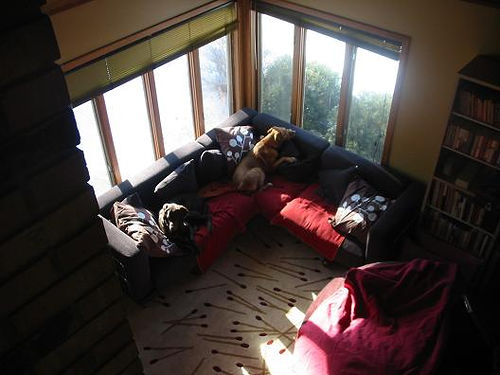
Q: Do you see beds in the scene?
A: No, there are no beds.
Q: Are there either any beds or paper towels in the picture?
A: No, there are no beds or paper towels.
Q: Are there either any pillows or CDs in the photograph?
A: Yes, there is a pillow.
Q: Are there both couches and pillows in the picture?
A: Yes, there are both a pillow and a couch.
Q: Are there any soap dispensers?
A: No, there are no soap dispensers.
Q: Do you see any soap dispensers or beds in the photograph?
A: No, there are no soap dispensers or beds.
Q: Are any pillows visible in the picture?
A: Yes, there is a pillow.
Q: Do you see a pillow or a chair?
A: Yes, there is a pillow.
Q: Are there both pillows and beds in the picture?
A: No, there is a pillow but no beds.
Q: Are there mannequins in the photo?
A: No, there are no mannequins.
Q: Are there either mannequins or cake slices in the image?
A: No, there are no mannequins or cake slices.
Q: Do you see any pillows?
A: Yes, there is a pillow.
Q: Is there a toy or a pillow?
A: Yes, there is a pillow.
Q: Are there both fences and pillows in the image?
A: No, there is a pillow but no fences.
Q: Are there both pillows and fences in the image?
A: No, there is a pillow but no fences.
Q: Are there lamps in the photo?
A: No, there are no lamps.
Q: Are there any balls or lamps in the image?
A: No, there are no lamps or balls.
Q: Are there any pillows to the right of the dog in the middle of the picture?
A: Yes, there is a pillow to the right of the dog.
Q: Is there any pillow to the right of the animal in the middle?
A: Yes, there is a pillow to the right of the dog.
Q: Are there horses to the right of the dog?
A: No, there is a pillow to the right of the dog.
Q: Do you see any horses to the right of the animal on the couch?
A: No, there is a pillow to the right of the dog.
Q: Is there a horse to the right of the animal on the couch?
A: No, there is a pillow to the right of the dog.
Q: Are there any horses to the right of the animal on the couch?
A: No, there is a pillow to the right of the dog.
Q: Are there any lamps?
A: No, there are no lamps.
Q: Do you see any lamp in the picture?
A: No, there are no lamps.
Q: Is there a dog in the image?
A: Yes, there is a dog.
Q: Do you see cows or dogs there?
A: Yes, there is a dog.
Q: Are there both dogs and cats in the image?
A: No, there is a dog but no cats.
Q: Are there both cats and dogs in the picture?
A: No, there is a dog but no cats.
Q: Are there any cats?
A: No, there are no cats.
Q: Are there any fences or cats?
A: No, there are no cats or fences.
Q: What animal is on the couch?
A: The animal is a dog.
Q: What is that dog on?
A: The dog is on the couch.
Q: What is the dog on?
A: The dog is on the couch.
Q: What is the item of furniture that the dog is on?
A: The piece of furniture is a couch.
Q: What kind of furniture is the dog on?
A: The dog is on the couch.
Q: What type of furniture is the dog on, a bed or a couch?
A: The dog is on a couch.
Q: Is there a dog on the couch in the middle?
A: Yes, there is a dog on the couch.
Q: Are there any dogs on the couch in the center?
A: Yes, there is a dog on the couch.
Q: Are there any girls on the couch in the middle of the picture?
A: No, there is a dog on the couch.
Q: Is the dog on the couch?
A: Yes, the dog is on the couch.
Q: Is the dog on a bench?
A: No, the dog is on the couch.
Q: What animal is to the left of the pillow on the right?
A: The animal is a dog.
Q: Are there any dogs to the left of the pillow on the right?
A: Yes, there is a dog to the left of the pillow.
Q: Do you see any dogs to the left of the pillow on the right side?
A: Yes, there is a dog to the left of the pillow.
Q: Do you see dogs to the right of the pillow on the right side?
A: No, the dog is to the left of the pillow.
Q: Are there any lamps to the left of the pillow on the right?
A: No, there is a dog to the left of the pillow.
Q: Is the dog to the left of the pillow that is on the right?
A: Yes, the dog is to the left of the pillow.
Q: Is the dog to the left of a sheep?
A: No, the dog is to the left of the pillow.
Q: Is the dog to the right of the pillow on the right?
A: No, the dog is to the left of the pillow.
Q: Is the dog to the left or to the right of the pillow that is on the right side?
A: The dog is to the left of the pillow.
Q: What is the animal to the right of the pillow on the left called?
A: The animal is a dog.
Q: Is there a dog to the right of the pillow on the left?
A: Yes, there is a dog to the right of the pillow.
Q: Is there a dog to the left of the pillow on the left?
A: No, the dog is to the right of the pillow.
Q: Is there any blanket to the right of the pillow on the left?
A: No, there is a dog to the right of the pillow.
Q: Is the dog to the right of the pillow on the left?
A: Yes, the dog is to the right of the pillow.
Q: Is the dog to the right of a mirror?
A: No, the dog is to the right of the pillow.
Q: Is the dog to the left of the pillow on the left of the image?
A: No, the dog is to the right of the pillow.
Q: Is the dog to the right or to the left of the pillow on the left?
A: The dog is to the right of the pillow.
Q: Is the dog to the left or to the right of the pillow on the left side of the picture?
A: The dog is to the right of the pillow.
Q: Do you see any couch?
A: Yes, there is a couch.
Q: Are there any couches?
A: Yes, there is a couch.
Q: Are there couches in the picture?
A: Yes, there is a couch.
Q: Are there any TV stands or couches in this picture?
A: Yes, there is a couch.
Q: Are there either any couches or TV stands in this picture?
A: Yes, there is a couch.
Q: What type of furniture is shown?
A: The furniture is a couch.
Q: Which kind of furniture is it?
A: The piece of furniture is a couch.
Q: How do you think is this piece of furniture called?
A: That is a couch.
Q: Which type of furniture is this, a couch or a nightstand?
A: That is a couch.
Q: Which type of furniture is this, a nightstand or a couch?
A: That is a couch.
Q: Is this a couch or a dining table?
A: This is a couch.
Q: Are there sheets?
A: No, there are no sheets.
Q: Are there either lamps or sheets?
A: No, there are no sheets or lamps.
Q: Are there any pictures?
A: No, there are no pictures.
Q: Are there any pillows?
A: Yes, there is a pillow.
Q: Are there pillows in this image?
A: Yes, there is a pillow.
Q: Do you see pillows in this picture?
A: Yes, there is a pillow.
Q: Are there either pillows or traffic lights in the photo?
A: Yes, there is a pillow.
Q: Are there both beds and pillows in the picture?
A: No, there is a pillow but no beds.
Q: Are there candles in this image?
A: No, there are no candles.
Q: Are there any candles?
A: No, there are no candles.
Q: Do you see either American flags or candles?
A: No, there are no candles or American flags.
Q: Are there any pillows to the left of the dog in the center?
A: Yes, there is a pillow to the left of the dog.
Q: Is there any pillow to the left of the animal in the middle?
A: Yes, there is a pillow to the left of the dog.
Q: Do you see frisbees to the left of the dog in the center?
A: No, there is a pillow to the left of the dog.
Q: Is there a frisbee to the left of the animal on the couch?
A: No, there is a pillow to the left of the dog.